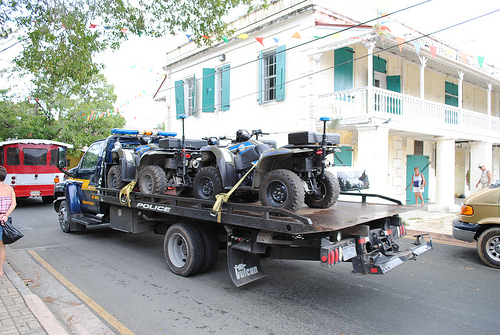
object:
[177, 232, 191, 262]
part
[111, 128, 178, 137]
lights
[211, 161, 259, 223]
rope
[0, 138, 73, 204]
bus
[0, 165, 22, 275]
woman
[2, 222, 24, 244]
black bag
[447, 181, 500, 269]
minivan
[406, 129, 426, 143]
part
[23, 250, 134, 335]
line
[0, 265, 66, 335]
sidewalk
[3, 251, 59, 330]
edge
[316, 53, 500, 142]
balcony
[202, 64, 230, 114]
doors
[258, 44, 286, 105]
doors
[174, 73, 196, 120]
doors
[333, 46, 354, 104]
doors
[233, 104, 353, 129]
floor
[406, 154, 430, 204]
door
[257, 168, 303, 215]
wheel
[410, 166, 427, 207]
man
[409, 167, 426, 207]
woman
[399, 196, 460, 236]
sidewalk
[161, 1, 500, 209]
building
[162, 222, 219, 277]
wheel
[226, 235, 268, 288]
flap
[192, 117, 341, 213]
bike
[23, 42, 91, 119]
tree/part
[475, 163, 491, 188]
people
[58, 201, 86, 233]
wheel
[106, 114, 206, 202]
bikes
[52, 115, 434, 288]
trailer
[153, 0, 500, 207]
story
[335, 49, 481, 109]
floor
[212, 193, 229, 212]
tie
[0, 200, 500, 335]
road